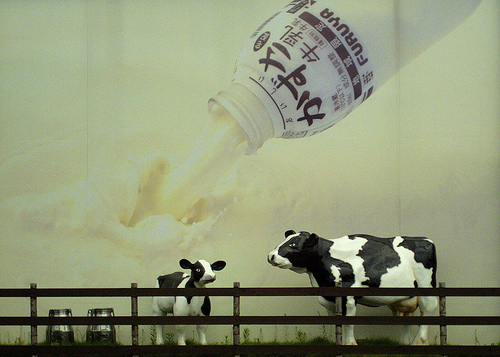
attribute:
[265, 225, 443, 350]
cow — large, black, white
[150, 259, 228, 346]
cow — small, black, little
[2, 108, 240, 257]
milk — pouring, poured out, white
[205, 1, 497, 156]
bottle — white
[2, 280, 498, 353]
fence — wood, brown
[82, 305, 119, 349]
tub — silver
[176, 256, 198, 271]
ear — black